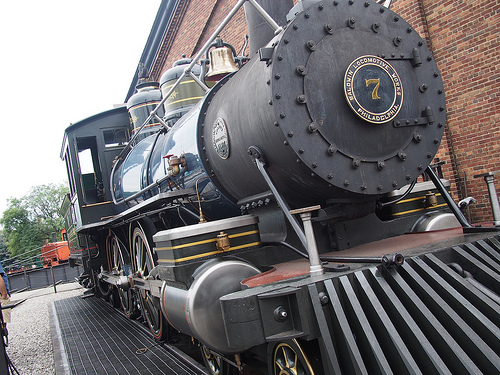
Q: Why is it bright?
A: Sunny.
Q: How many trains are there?
A: One.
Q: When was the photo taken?
A: Day time.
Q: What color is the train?
A: Black.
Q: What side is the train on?
A: Right side.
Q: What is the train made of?
A: Metal.